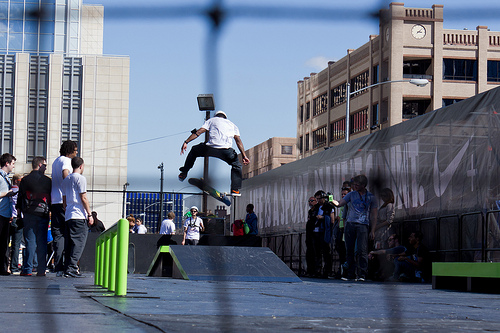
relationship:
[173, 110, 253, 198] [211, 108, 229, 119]
man wears hat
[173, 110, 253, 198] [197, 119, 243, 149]
man wears white shirt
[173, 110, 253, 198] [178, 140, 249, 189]
man wears jeans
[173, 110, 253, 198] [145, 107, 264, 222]
man doing trick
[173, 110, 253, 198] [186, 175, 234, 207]
man rides skateboard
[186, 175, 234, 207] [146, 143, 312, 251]
skateboard in air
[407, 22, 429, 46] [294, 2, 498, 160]
clock on building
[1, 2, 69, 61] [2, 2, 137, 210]
window on front of building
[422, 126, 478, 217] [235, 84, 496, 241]
nike logo on banner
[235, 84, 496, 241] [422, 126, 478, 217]
banner has nike logo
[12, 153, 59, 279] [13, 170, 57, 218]
man wears black jacket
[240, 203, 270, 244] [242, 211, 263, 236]
man wears blue shirt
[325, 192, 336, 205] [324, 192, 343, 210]
camera being held